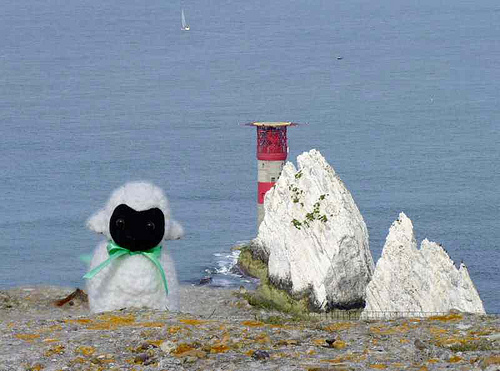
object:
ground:
[0, 284, 499, 370]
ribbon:
[81, 239, 169, 293]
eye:
[146, 221, 155, 229]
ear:
[167, 219, 181, 240]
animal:
[86, 180, 183, 313]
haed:
[84, 179, 183, 248]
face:
[109, 203, 164, 250]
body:
[84, 239, 176, 311]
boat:
[179, 9, 190, 30]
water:
[2, 1, 499, 284]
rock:
[248, 148, 376, 311]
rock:
[362, 209, 485, 317]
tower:
[245, 120, 296, 235]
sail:
[181, 6, 187, 26]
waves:
[210, 245, 242, 282]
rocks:
[236, 245, 260, 278]